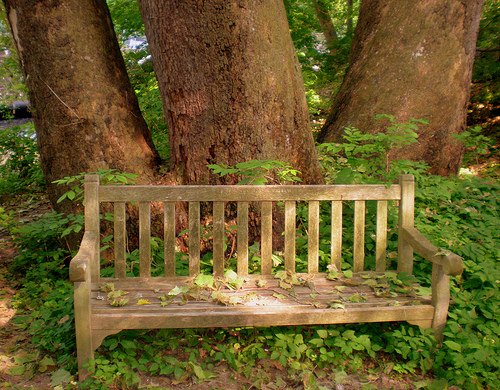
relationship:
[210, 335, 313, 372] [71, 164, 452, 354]
plant under bench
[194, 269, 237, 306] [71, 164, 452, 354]
leaves on bench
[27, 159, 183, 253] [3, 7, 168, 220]
stump of tree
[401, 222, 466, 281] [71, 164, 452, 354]
arm of bench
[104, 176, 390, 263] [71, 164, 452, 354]
back of bench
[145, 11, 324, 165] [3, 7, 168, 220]
trunk of tree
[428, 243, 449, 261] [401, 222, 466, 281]
leaf on arm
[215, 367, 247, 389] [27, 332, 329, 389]
dirt on ground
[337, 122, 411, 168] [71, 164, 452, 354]
plant behind bench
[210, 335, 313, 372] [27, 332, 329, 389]
plant on ground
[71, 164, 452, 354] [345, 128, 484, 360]
bench in bushes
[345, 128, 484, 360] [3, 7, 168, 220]
bushes by tree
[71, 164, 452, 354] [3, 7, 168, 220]
bench by tree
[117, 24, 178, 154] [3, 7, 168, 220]
bushes behind tree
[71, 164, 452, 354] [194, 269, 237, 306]
bench has leaves